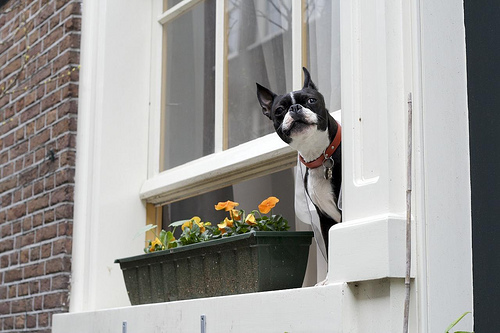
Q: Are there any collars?
A: Yes, there is a collar.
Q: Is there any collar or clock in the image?
A: Yes, there is a collar.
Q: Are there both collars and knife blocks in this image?
A: No, there is a collar but no knife blocks.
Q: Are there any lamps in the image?
A: No, there are no lamps.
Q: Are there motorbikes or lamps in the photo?
A: No, there are no lamps or motorbikes.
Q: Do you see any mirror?
A: No, there are no mirrors.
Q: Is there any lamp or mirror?
A: No, there are no mirrors or lamps.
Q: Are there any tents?
A: No, there are no tents.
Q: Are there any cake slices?
A: No, there are no cake slices.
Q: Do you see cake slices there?
A: No, there are no cake slices.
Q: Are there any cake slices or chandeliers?
A: No, there are no cake slices or chandeliers.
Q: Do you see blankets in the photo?
A: No, there are no blankets.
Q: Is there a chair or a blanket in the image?
A: No, there are no blankets or chairs.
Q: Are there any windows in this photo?
A: Yes, there is a window.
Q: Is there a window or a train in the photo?
A: Yes, there is a window.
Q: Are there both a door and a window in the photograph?
A: No, there is a window but no doors.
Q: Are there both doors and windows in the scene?
A: No, there is a window but no doors.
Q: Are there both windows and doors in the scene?
A: No, there is a window but no doors.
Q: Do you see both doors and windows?
A: No, there is a window but no doors.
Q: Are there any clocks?
A: No, there are no clocks.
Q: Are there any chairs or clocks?
A: No, there are no clocks or chairs.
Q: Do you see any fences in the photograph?
A: No, there are no fences.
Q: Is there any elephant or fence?
A: No, there are no fences or elephants.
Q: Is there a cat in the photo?
A: No, there are no cats.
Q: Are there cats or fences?
A: No, there are no cats or fences.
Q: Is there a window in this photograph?
A: Yes, there is a window.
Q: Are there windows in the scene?
A: Yes, there is a window.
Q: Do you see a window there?
A: Yes, there is a window.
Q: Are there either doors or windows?
A: Yes, there is a window.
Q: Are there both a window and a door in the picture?
A: No, there is a window but no doors.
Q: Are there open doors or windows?
A: Yes, there is an open window.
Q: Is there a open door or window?
A: Yes, there is an open window.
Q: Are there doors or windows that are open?
A: Yes, the window is open.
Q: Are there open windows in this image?
A: Yes, there is an open window.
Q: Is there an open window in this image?
A: Yes, there is an open window.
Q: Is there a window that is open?
A: Yes, there is a window that is open.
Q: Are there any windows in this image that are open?
A: Yes, there is a window that is open.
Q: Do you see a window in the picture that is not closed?
A: Yes, there is a open window.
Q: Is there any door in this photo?
A: No, there are no doors.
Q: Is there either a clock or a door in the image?
A: No, there are no doors or clocks.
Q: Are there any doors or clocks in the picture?
A: No, there are no doors or clocks.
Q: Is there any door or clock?
A: No, there are no doors or clocks.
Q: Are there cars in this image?
A: No, there are no cars.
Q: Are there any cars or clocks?
A: No, there are no cars or clocks.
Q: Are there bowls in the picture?
A: No, there are no bowls.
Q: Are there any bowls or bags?
A: No, there are no bowls or bags.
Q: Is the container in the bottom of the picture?
A: Yes, the container is in the bottom of the image.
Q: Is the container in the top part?
A: No, the container is in the bottom of the image.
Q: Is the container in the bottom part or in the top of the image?
A: The container is in the bottom of the image.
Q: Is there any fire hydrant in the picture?
A: No, there are no fire hydrants.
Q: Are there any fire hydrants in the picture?
A: No, there are no fire hydrants.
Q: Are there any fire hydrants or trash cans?
A: No, there are no fire hydrants or trash cans.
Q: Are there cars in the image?
A: No, there are no cars.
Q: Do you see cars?
A: No, there are no cars.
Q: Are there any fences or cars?
A: No, there are no cars or fences.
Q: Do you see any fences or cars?
A: No, there are no cars or fences.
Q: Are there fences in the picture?
A: No, there are no fences.